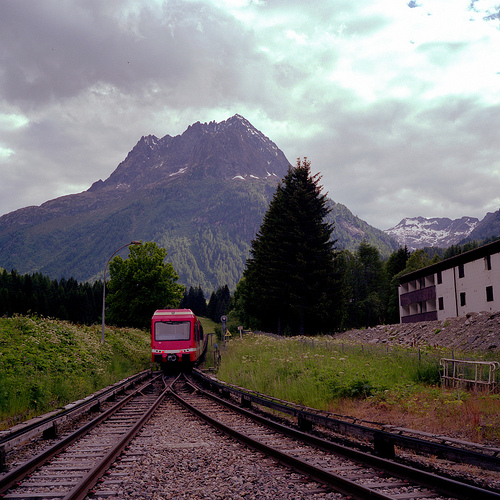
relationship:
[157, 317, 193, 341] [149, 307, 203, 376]
windshield on train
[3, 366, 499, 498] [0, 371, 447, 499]
railroad tracks in rocks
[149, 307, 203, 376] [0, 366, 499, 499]
train on railroad tracks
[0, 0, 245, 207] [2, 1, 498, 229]
clouds in sky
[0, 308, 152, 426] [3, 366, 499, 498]
grass next to railroad tracks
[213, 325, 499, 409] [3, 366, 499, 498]
grass next to railroad tracks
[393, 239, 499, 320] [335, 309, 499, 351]
building on hill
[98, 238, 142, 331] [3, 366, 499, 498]
lamp over railroad tracks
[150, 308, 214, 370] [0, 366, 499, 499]
train on railroad tracks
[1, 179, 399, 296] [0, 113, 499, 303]
trees on mountain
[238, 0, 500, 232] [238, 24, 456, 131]
clouds in sky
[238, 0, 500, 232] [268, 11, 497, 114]
clouds in sky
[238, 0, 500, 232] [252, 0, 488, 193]
clouds in sky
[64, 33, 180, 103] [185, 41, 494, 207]
clouds in sky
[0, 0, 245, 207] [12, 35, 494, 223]
clouds in sky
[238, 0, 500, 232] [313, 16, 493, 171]
clouds in sky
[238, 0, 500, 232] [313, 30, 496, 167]
clouds in sky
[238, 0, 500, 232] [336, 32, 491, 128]
clouds in sky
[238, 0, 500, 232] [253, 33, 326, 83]
clouds in sky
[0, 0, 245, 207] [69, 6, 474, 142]
clouds in sky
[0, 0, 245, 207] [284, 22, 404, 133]
clouds in sky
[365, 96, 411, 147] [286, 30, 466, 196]
clouds in sky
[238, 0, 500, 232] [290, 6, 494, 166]
clouds in sky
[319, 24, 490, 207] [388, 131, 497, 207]
sky in clouds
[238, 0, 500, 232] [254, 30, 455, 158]
clouds in sky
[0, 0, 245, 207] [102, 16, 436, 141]
clouds in sky